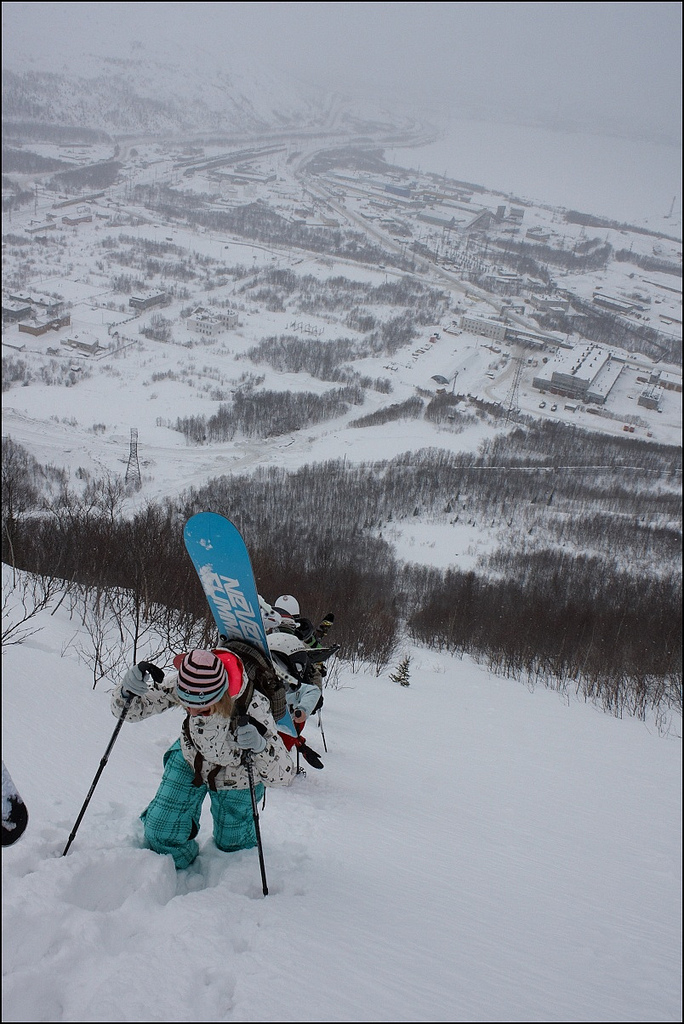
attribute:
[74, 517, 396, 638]
trees — dead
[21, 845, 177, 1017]
foot steps — in snow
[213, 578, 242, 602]
letter —  white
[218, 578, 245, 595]
letter —  white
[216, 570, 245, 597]
letter —  white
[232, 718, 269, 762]
glove — white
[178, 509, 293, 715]
board — huge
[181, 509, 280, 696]
board — blue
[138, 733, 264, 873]
pants — teal, gray, plaid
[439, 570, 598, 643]
trees — dead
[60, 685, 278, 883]
ski poles — BLACK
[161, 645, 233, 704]
knit cap — STRIPED, PINK, BROWN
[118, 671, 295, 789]
jacket — WHITE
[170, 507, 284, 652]
snowboard — BLUE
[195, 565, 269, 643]
lettering — WHITE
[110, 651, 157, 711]
glove — LIGHT GRAY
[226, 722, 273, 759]
glove — LIGHT GRAY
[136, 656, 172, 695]
strap — BLACK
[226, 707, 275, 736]
strap — BLACK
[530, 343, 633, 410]
building — LARGE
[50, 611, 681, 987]
hill — LARGE